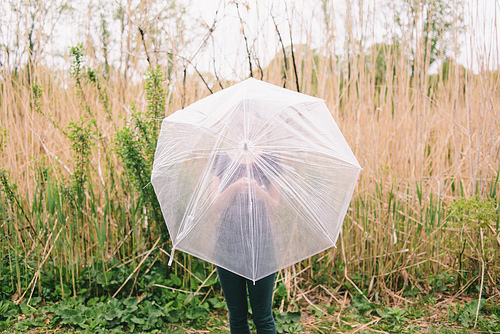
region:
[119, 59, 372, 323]
woman behind an umbrella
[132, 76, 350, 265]
umbrella held by woman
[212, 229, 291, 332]
pants on the woman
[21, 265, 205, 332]
plants on the ground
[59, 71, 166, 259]
tall plants on the ground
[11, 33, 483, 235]
brown plants behind the woman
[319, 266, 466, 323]
sticks of plant on ground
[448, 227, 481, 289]
twig on the ground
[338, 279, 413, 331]
plants on the ground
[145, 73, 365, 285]
umbrella is open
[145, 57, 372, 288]
umbrella is clear in color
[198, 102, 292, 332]
woman is behind umbrella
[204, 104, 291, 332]
woman has black pants on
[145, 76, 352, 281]
umbrella is in front of woman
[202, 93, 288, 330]
woman is holding the umbrella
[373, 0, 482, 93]
tree is behind woman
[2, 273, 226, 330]
weeds are green in color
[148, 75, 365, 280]
umbrella is protecting woman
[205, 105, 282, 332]
woman is white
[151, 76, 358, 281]
the umbrella is clear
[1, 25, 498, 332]
a lot of tall bushes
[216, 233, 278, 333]
the pants are blue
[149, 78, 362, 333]
woman with an umbrella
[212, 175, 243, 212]
arm of a woman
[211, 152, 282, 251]
the shirt is purple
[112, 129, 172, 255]
a tall green plant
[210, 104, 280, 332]
a girl is standing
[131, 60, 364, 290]
clear open umbrella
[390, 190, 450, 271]
long green and yellow grass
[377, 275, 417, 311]
long green and yellow grass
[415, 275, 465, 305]
long green and yellow grass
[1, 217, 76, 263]
long green and yellow grass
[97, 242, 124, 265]
long green and yellow grass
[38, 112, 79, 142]
long green and yellow grass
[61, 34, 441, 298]
a person under an umbrella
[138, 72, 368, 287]
the umbrella looks white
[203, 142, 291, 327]
the girl is wearing a purple shirt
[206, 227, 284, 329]
she has on blue jeans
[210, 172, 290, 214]
her hands are folded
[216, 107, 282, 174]
her face cannot be seen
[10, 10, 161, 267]
this is tall grass behind the girl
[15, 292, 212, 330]
weeds on the ground